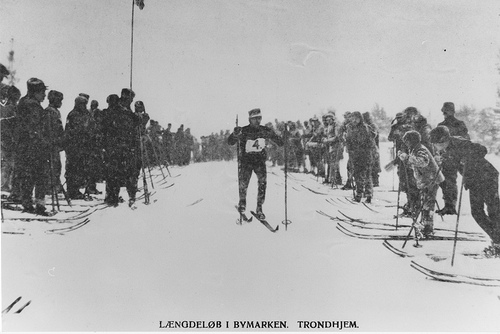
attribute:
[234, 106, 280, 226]
man — short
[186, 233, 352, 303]
snow — some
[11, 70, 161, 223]
group — large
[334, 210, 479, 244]
skis — black, long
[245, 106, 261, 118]
hat — furry, small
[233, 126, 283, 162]
shirt — long-sleeved, black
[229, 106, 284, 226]
person — small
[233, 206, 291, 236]
skis — long, black, curved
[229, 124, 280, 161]
shirt — one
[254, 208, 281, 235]
ski — one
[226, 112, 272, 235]
pole — ski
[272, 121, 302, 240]
pole — ski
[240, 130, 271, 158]
sign — number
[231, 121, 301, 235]
poles — ski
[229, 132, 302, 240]
skis — set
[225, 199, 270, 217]
feet — man's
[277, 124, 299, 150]
hand — man's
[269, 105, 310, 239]
pole — ski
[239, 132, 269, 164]
bib — white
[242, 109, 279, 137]
head — man's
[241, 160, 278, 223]
legs — man's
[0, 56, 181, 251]
skiers — group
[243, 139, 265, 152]
bib — white